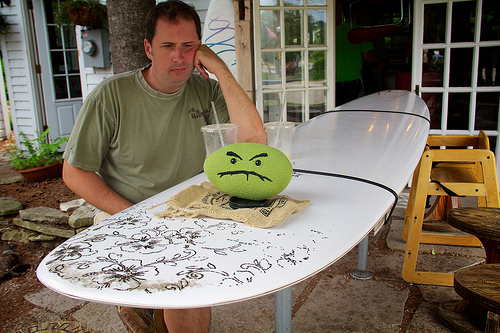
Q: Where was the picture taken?
A: It was taken at the porch.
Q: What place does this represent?
A: It represents the porch.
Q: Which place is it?
A: It is a porch.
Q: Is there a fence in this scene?
A: No, there are no fences.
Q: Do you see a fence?
A: No, there are no fences.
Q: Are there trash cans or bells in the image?
A: No, there are no bells or trash cans.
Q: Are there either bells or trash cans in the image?
A: No, there are no bells or trash cans.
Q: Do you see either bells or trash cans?
A: No, there are no bells or trash cans.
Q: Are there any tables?
A: Yes, there is a table.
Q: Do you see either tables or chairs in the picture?
A: Yes, there is a table.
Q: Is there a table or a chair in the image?
A: Yes, there is a table.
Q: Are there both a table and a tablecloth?
A: No, there is a table but no tablecloths.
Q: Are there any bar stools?
A: No, there are no bar stools.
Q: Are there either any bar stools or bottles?
A: No, there are no bar stools or bottles.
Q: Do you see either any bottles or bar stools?
A: No, there are no bar stools or bottles.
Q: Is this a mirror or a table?
A: This is a table.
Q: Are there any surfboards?
A: Yes, there is a surfboard.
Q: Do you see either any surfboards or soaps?
A: Yes, there is a surfboard.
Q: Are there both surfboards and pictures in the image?
A: No, there is a surfboard but no pictures.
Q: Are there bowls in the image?
A: No, there are no bowls.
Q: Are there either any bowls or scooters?
A: No, there are no bowls or scooters.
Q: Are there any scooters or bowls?
A: No, there are no bowls or scooters.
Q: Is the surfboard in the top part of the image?
A: Yes, the surfboard is in the top of the image.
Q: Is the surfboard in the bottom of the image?
A: No, the surfboard is in the top of the image.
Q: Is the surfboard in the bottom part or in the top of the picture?
A: The surfboard is in the top of the image.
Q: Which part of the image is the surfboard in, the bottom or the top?
A: The surfboard is in the top of the image.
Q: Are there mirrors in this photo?
A: No, there are no mirrors.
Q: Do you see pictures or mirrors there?
A: No, there are no mirrors or pictures.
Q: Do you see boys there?
A: No, there are no boys.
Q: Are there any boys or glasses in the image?
A: No, there are no boys or glasses.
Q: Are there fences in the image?
A: No, there are no fences.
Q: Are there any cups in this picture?
A: Yes, there is a cup.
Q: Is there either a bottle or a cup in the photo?
A: Yes, there is a cup.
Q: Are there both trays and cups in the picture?
A: No, there is a cup but no trays.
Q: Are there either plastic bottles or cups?
A: Yes, there is a plastic cup.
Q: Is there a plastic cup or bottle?
A: Yes, there is a plastic cup.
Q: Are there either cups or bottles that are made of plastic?
A: Yes, the cup is made of plastic.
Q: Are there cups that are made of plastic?
A: Yes, there is a cup that is made of plastic.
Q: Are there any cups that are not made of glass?
A: Yes, there is a cup that is made of plastic.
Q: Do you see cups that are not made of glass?
A: Yes, there is a cup that is made of plastic.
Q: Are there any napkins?
A: No, there are no napkins.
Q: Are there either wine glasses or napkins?
A: No, there are no napkins or wine glasses.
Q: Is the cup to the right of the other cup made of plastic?
A: Yes, the cup is made of plastic.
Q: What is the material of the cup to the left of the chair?
A: The cup is made of plastic.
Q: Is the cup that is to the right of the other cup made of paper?
A: No, the cup is made of plastic.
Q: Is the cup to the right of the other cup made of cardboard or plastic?
A: The cup is made of plastic.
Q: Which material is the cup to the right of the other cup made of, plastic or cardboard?
A: The cup is made of plastic.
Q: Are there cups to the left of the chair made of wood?
A: Yes, there is a cup to the left of the chair.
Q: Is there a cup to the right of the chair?
A: No, the cup is to the left of the chair.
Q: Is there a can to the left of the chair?
A: No, there is a cup to the left of the chair.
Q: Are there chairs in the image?
A: Yes, there is a chair.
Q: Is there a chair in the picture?
A: Yes, there is a chair.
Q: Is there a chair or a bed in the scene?
A: Yes, there is a chair.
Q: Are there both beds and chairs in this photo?
A: No, there is a chair but no beds.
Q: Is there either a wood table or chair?
A: Yes, there is a wood chair.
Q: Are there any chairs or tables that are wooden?
A: Yes, the chair is wooden.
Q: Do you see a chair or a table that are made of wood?
A: Yes, the chair is made of wood.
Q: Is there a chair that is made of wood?
A: Yes, there is a chair that is made of wood.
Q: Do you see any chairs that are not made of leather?
A: Yes, there is a chair that is made of wood.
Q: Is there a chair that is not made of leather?
A: Yes, there is a chair that is made of wood.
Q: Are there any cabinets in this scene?
A: No, there are no cabinets.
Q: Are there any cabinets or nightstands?
A: No, there are no cabinets or nightstands.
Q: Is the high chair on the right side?
A: Yes, the chair is on the right of the image.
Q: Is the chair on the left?
A: No, the chair is on the right of the image.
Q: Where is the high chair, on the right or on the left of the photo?
A: The chair is on the right of the image.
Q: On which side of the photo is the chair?
A: The chair is on the right of the image.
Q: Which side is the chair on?
A: The chair is on the right of the image.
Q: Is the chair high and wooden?
A: Yes, the chair is high and wooden.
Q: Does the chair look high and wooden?
A: Yes, the chair is high and wooden.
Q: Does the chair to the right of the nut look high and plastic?
A: No, the chair is high but wooden.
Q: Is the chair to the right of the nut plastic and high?
A: No, the chair is high but wooden.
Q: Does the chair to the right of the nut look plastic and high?
A: No, the chair is high but wooden.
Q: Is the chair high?
A: Yes, the chair is high.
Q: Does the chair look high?
A: Yes, the chair is high.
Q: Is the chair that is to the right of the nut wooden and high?
A: Yes, the chair is wooden and high.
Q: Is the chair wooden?
A: Yes, the chair is wooden.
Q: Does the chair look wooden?
A: Yes, the chair is wooden.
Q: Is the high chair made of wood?
A: Yes, the chair is made of wood.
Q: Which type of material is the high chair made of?
A: The chair is made of wood.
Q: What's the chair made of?
A: The chair is made of wood.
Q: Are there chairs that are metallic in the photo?
A: No, there is a chair but it is wooden.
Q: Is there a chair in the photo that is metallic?
A: No, there is a chair but it is wooden.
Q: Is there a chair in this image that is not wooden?
A: No, there is a chair but it is wooden.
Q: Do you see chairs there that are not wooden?
A: No, there is a chair but it is wooden.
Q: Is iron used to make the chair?
A: No, the chair is made of wood.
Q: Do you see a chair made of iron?
A: No, there is a chair but it is made of wood.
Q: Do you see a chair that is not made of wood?
A: No, there is a chair but it is made of wood.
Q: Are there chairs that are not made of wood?
A: No, there is a chair but it is made of wood.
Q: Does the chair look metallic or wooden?
A: The chair is wooden.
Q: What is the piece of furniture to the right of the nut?
A: The piece of furniture is a chair.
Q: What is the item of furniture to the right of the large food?
A: The piece of furniture is a chair.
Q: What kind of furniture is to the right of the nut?
A: The piece of furniture is a chair.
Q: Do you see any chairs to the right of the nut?
A: Yes, there is a chair to the right of the nut.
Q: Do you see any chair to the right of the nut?
A: Yes, there is a chair to the right of the nut.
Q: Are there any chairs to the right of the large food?
A: Yes, there is a chair to the right of the nut.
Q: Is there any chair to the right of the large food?
A: Yes, there is a chair to the right of the nut.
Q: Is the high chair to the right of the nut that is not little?
A: Yes, the chair is to the right of the nut.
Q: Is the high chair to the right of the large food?
A: Yes, the chair is to the right of the nut.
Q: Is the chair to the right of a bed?
A: No, the chair is to the right of the nut.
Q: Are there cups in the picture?
A: Yes, there is a cup.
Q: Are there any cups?
A: Yes, there is a cup.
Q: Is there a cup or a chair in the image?
A: Yes, there is a cup.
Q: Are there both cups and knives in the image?
A: No, there is a cup but no knives.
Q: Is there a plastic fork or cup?
A: Yes, there is a plastic cup.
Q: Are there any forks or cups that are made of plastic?
A: Yes, the cup is made of plastic.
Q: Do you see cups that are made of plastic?
A: Yes, there is a cup that is made of plastic.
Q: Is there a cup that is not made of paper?
A: Yes, there is a cup that is made of plastic.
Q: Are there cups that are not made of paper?
A: Yes, there is a cup that is made of plastic.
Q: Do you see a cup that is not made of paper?
A: Yes, there is a cup that is made of plastic.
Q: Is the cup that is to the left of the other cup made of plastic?
A: Yes, the cup is made of plastic.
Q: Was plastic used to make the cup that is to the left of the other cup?
A: Yes, the cup is made of plastic.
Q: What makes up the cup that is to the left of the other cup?
A: The cup is made of plastic.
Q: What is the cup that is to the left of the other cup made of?
A: The cup is made of plastic.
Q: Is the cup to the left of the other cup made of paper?
A: No, the cup is made of plastic.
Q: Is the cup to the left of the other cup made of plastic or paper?
A: The cup is made of plastic.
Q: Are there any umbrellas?
A: No, there are no umbrellas.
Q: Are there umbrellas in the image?
A: No, there are no umbrellas.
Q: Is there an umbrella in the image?
A: No, there are no umbrellas.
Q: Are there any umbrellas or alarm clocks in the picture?
A: No, there are no umbrellas or alarm clocks.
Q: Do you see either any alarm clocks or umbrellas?
A: No, there are no umbrellas or alarm clocks.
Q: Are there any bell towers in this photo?
A: No, there are no bell towers.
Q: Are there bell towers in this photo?
A: No, there are no bell towers.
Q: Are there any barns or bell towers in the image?
A: No, there are no bell towers or barns.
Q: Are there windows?
A: Yes, there is a window.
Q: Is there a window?
A: Yes, there is a window.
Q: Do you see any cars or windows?
A: Yes, there is a window.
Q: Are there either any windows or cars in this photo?
A: Yes, there is a window.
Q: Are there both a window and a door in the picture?
A: Yes, there are both a window and a door.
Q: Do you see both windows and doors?
A: Yes, there are both a window and a door.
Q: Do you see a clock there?
A: No, there are no clocks.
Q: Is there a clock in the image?
A: No, there are no clocks.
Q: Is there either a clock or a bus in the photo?
A: No, there are no clocks or buses.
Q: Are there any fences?
A: No, there are no fences.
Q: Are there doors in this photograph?
A: Yes, there is a door.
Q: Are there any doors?
A: Yes, there is a door.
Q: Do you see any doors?
A: Yes, there is a door.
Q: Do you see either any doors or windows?
A: Yes, there is a door.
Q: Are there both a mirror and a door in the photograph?
A: No, there is a door but no mirrors.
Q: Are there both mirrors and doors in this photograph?
A: No, there is a door but no mirrors.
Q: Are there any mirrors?
A: No, there are no mirrors.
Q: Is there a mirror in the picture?
A: No, there are no mirrors.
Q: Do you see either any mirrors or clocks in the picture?
A: No, there are no mirrors or clocks.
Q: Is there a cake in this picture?
A: No, there are no cakes.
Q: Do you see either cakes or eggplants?
A: No, there are no cakes or eggplants.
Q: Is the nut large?
A: Yes, the nut is large.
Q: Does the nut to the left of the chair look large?
A: Yes, the nut is large.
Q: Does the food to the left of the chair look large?
A: Yes, the nut is large.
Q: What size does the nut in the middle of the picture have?
A: The nut has large size.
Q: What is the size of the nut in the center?
A: The nut is large.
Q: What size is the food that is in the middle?
A: The nut is large.